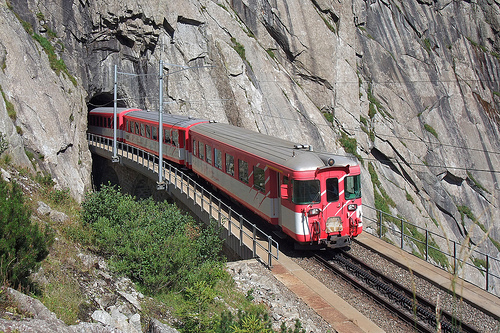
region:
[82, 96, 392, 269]
train on the tracks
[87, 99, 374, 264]
red and silver train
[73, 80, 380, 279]
train coming out of a tunnel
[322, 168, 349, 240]
white stripes on the door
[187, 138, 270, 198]
row of windows on the side of the train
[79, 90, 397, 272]
three train cars are visible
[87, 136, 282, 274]
railing on the side of the tracks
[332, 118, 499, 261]
green plants on the side of the cliff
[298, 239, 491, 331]
gravel around the train tracks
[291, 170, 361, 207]
windows on the front of the train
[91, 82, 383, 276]
a red train going down the tracks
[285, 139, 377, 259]
the front part of a train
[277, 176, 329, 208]
the window on the front part of the train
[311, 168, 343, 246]
the front door of a train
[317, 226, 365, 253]
the front step of a red train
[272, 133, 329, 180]
the gray roof of a train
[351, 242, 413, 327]
a bunch of skinny black train tracks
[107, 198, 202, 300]
a patch of green trees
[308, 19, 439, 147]
a gray colored rocky cliff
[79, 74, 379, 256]
a train going through a tunnel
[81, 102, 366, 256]
red and silver train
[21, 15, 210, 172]
tunnel goes through a mountain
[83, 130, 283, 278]
railings next to a mountain railway track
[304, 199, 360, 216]
headlamps on the front of a train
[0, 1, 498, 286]
sheer grey rock on a mountainside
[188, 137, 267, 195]
windows in a train carriage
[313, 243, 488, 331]
metal parallel train tracks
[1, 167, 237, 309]
shrubs growing on a mountainside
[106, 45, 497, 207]
power cables above a railway line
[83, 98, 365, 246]
train coming down track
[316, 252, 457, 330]
track with train on it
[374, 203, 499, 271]
rail on side of track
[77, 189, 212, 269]
bushes next to track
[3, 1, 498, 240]
stone wall near track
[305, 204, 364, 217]
lights on the train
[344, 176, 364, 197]
window in front of train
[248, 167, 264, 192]
window on side on train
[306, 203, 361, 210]
lights on the train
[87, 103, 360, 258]
red train with white stripe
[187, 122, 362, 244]
the front train cart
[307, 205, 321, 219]
front right light of train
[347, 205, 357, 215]
front left light of train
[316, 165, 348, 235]
red door on front of train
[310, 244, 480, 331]
tracks of a railroad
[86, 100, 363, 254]
a train on tracks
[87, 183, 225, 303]
green bushes beside tracks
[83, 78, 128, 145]
a train tunnel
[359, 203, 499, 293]
railing beside train tacks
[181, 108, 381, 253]
red train on the tracks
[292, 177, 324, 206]
window on the train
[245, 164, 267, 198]
window on the train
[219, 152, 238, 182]
window on the train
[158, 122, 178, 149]
window on the train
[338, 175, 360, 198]
window on the train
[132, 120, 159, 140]
window on the train